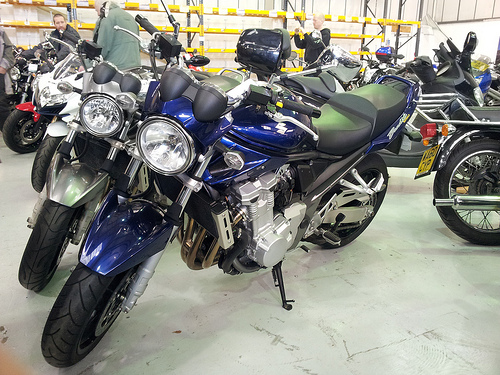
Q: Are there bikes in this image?
A: Yes, there is a bike.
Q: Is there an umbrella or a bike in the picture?
A: Yes, there is a bike.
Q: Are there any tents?
A: No, there are no tents.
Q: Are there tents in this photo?
A: No, there are no tents.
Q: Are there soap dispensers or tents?
A: No, there are no tents or soap dispensers.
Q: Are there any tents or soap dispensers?
A: No, there are no tents or soap dispensers.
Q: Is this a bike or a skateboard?
A: This is a bike.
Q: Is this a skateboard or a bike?
A: This is a bike.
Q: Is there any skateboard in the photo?
A: No, there are no skateboards.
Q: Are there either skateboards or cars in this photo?
A: No, there are no skateboards or cars.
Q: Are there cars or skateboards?
A: No, there are no skateboards or cars.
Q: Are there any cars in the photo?
A: No, there are no cars.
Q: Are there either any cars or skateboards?
A: No, there are no cars or skateboards.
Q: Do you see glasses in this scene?
A: No, there are no glasses.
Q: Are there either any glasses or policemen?
A: No, there are no glasses or policemen.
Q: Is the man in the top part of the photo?
A: Yes, the man is in the top of the image.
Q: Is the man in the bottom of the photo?
A: No, the man is in the top of the image.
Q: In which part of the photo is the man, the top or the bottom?
A: The man is in the top of the image.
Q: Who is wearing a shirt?
A: The man is wearing a shirt.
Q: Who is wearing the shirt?
A: The man is wearing a shirt.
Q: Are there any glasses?
A: No, there are no glasses.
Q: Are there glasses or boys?
A: No, there are no glasses or boys.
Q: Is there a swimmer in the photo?
A: No, there are no swimmers.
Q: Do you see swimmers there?
A: No, there are no swimmers.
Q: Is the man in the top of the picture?
A: Yes, the man is in the top of the image.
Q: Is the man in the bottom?
A: No, the man is in the top of the image.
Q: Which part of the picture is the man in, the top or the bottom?
A: The man is in the top of the image.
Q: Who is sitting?
A: The man is sitting.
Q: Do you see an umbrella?
A: No, there are no umbrellas.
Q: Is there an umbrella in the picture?
A: No, there are no umbrellas.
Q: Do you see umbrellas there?
A: No, there are no umbrellas.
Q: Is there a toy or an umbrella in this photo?
A: No, there are no umbrellas or toys.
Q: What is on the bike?
A: The seat is on the bike.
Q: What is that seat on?
A: The seat is on the bike.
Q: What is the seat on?
A: The seat is on the bike.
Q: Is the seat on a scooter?
A: No, the seat is on the bike.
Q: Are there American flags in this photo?
A: No, there are no American flags.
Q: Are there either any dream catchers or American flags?
A: No, there are no American flags or dream catchers.